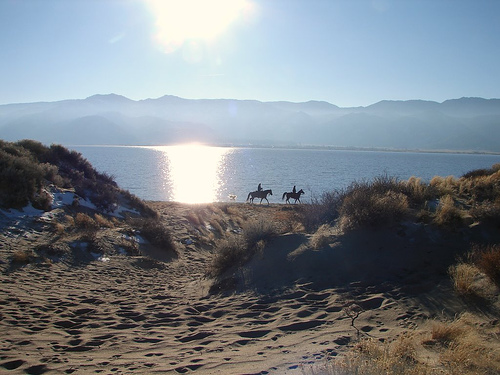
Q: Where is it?
A: This is at the shore.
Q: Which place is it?
A: It is a shore.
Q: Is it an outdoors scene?
A: Yes, it is outdoors.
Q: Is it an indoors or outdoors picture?
A: It is outdoors.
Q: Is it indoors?
A: No, it is outdoors.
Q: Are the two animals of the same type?
A: Yes, all the animals are horses.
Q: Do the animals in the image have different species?
A: No, all the animals are horses.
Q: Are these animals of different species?
A: No, all the animals are horses.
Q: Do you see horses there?
A: Yes, there is a horse.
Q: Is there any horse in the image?
A: Yes, there is a horse.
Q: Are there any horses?
A: Yes, there is a horse.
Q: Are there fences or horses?
A: Yes, there is a horse.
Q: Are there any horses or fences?
A: Yes, there is a horse.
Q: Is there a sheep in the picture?
A: No, there is no sheep.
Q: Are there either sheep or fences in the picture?
A: No, there are no sheep or fences.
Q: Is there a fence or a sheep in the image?
A: No, there are no sheep or fences.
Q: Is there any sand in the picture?
A: Yes, there is sand.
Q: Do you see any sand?
A: Yes, there is sand.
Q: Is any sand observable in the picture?
A: Yes, there is sand.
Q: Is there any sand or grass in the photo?
A: Yes, there is sand.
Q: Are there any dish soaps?
A: No, there are no dish soaps.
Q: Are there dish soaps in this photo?
A: No, there are no dish soaps.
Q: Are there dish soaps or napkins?
A: No, there are no dish soaps or napkins.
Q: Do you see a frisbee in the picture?
A: No, there are no frisbees.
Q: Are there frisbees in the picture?
A: No, there are no frisbees.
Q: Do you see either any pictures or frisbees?
A: No, there are no frisbees or pictures.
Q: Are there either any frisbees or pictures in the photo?
A: No, there are no frisbees or pictures.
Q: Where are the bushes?
A: The bushes are on the shore.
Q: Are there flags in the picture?
A: No, there are no flags.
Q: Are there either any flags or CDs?
A: No, there are no flags or cds.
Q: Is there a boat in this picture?
A: No, there are no boats.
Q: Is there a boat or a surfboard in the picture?
A: No, there are no boats or surfboards.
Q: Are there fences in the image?
A: No, there are no fences.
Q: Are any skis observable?
A: No, there are no skis.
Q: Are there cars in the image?
A: No, there are no cars.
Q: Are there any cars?
A: No, there are no cars.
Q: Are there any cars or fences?
A: No, there are no cars or fences.